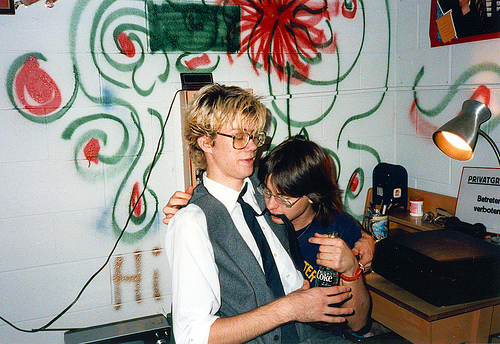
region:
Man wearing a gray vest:
[161, 74, 348, 341]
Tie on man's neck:
[229, 181, 302, 343]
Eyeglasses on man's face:
[201, 124, 267, 156]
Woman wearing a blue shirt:
[262, 134, 378, 343]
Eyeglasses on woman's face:
[246, 174, 306, 206]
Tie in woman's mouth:
[257, 199, 294, 235]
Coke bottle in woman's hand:
[302, 225, 343, 299]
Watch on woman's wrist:
[337, 254, 364, 289]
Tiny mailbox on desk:
[369, 152, 408, 213]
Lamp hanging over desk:
[432, 88, 499, 220]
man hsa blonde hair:
[152, 87, 284, 171]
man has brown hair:
[258, 128, 339, 226]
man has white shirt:
[207, 180, 319, 312]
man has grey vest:
[191, 188, 312, 318]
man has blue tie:
[235, 194, 299, 339]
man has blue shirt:
[284, 165, 392, 315]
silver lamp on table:
[441, 78, 498, 176]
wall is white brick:
[27, 127, 174, 251]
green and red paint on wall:
[35, 0, 229, 175]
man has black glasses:
[198, 111, 245, 155]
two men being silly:
[152, 88, 379, 342]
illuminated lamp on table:
[428, 81, 495, 189]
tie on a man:
[236, 195, 293, 302]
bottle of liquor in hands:
[303, 228, 343, 329]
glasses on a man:
[210, 125, 274, 151]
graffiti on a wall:
[13, 28, 151, 258]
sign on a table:
[446, 154, 496, 243]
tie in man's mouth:
[257, 205, 297, 234]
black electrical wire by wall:
[13, 272, 97, 342]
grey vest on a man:
[196, 188, 263, 320]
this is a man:
[173, 93, 269, 312]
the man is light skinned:
[210, 143, 233, 168]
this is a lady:
[269, 159, 359, 293]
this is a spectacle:
[226, 130, 268, 147]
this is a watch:
[342, 269, 378, 281]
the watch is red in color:
[345, 265, 362, 286]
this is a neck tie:
[240, 201, 268, 239]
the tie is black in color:
[242, 211, 264, 250]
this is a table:
[390, 295, 459, 325]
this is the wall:
[58, 45, 116, 180]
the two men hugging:
[162, 83, 375, 340]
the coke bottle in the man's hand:
[314, 232, 339, 288]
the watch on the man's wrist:
[339, 262, 365, 282]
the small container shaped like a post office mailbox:
[371, 162, 408, 213]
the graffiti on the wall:
[7, 0, 497, 307]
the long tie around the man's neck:
[237, 181, 304, 343]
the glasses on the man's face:
[255, 179, 303, 209]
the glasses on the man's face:
[212, 129, 265, 151]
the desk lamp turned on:
[432, 99, 499, 162]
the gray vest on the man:
[176, 167, 341, 342]